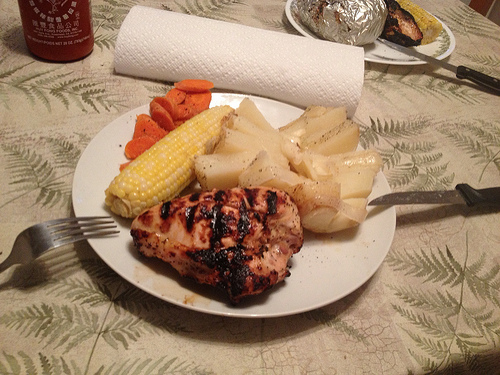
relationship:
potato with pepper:
[275, 125, 340, 208] [255, 165, 270, 176]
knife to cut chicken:
[376, 188, 499, 210] [156, 196, 293, 279]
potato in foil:
[315, 14, 366, 33] [355, 11, 366, 34]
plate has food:
[91, 156, 110, 192] [158, 107, 314, 270]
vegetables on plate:
[143, 98, 193, 191] [91, 156, 110, 192]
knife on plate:
[376, 188, 499, 210] [91, 156, 110, 192]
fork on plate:
[49, 205, 126, 259] [91, 156, 110, 192]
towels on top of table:
[120, 25, 353, 100] [381, 84, 465, 178]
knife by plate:
[376, 188, 499, 210] [91, 156, 110, 192]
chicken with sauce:
[156, 196, 293, 279] [208, 211, 231, 248]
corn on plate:
[121, 113, 196, 197] [91, 156, 110, 192]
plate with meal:
[91, 156, 110, 192] [132, 123, 263, 225]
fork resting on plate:
[49, 205, 126, 259] [91, 156, 110, 192]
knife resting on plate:
[376, 188, 499, 210] [91, 156, 110, 192]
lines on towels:
[196, 54, 238, 83] [120, 25, 353, 100]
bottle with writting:
[20, 1, 80, 51] [53, 21, 75, 34]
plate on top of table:
[91, 156, 110, 192] [381, 84, 465, 178]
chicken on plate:
[156, 196, 293, 279] [91, 156, 110, 192]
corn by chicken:
[121, 113, 196, 197] [156, 196, 293, 279]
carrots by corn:
[120, 84, 178, 158] [121, 113, 196, 197]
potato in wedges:
[275, 125, 340, 208] [298, 115, 352, 159]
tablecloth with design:
[11, 79, 55, 217] [21, 74, 96, 109]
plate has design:
[391, 44, 451, 66] [433, 41, 447, 60]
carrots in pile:
[120, 84, 178, 158] [154, 87, 188, 119]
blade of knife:
[385, 46, 450, 77] [440, 53, 478, 81]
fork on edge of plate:
[49, 205, 126, 259] [91, 156, 110, 192]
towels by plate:
[120, 25, 353, 100] [91, 156, 110, 192]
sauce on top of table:
[22, 3, 109, 63] [381, 84, 465, 178]